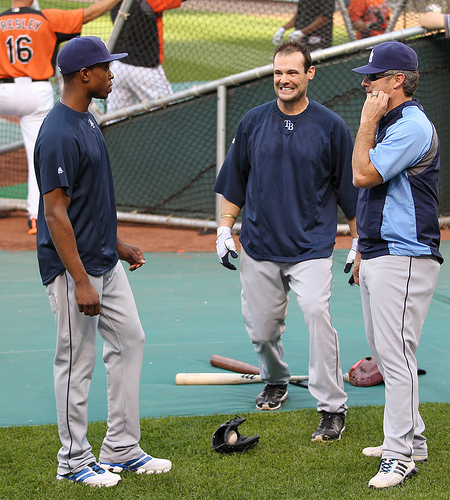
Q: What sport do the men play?
A: Baseball.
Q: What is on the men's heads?
A: Hats.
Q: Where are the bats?
A: On the ground.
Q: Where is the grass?
A: Under the men's feet.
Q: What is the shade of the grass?
A: Green.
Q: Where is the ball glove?
A: By the bat.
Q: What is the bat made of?
A: Wood.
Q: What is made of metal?
A: The fence.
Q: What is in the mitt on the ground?
A: Ball.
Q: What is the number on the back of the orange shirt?
A: 16.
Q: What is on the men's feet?
A: Sneakers.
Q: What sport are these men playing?
A: Baseball.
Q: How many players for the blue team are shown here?
A: Three.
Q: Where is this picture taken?
A: Baseball field.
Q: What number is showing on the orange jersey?
A: 16.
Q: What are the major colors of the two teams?
A: Blue and orange.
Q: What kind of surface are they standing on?
A: Grass.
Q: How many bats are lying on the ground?
A: Two.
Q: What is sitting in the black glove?
A: A baseball.